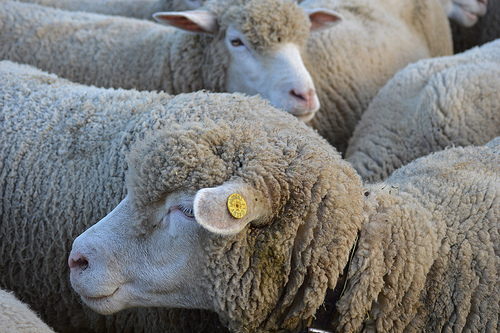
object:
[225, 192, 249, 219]
tag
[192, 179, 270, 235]
ear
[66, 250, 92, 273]
nose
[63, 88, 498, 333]
lamb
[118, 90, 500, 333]
fur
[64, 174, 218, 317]
face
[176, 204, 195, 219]
eyes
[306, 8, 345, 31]
ears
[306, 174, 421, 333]
neck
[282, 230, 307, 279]
folds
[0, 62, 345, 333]
wool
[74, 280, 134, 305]
mouth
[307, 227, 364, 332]
collar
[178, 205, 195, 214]
eyelash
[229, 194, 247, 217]
writing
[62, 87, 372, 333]
head